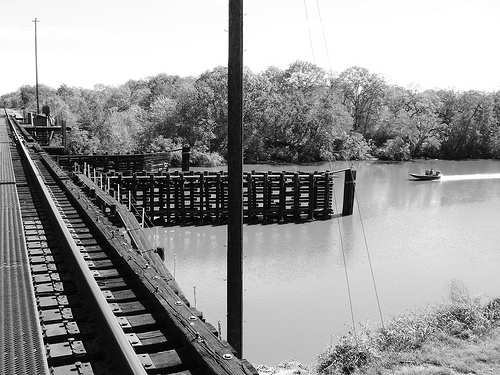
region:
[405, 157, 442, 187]
boat traveling in the waterway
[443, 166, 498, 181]
wake behind the boat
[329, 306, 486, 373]
bank of the river in the foreground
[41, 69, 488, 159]
trees on the bank of the river in the background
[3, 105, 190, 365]
train tracks on bridge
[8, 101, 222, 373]
bridge over top of the river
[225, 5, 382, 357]
utility poles with wires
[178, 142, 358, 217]
wood pillars in the water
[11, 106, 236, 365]
bolts in the bridge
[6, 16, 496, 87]
sky above the treeline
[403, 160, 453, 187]
The boat is in the water.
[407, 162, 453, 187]
The boat has a motor.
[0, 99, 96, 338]
No trains are on the train tracks.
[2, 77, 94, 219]
The trees are next to the train tracks.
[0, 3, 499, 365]
The picture is in black and white.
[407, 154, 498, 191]
The boat left tracks in the water.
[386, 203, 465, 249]
The water is flat.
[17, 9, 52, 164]
The pole is next to the train tracks.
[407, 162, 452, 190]
a boat in the water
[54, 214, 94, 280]
metal train rail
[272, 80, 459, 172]
trees beside the water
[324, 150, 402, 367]
cables fastened to the ground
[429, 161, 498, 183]
the wake of a boat in the water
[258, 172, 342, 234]
wooden piers in the water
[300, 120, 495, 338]
a river with a boat in it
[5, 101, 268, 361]
train tracks going across a river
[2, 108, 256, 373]
Wooden railway bridge crossing river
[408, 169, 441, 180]
Powerboat moving in river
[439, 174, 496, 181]
Wave wake caused by power boat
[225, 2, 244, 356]
Wooden utility power pole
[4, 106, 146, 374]
Metal railroad track on bridge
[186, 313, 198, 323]
Bolt and washer attaching bridge pieces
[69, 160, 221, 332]
Pedestrian walkway alongside of bridge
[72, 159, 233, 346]
Cable fence along bridge walkway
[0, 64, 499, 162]
Trees along river bank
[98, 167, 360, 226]
Channel fence for river navigation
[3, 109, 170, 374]
railroad tracks over water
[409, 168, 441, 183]
boat in a river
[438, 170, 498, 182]
wake created by a boat in a river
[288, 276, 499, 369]
grass on the near bank of the river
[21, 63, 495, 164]
trees on the far bank of a river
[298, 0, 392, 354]
wires connected to a pole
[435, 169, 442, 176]
motor on the back of a boat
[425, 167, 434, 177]
person in a boat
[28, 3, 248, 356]
two tall poles along railroad track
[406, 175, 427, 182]
shadow cast by a boat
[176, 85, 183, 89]
A green leaf on a plant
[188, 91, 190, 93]
A green leaf on a plant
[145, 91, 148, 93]
A green leaf on a plant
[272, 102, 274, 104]
A green leaf on a plant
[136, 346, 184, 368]
wooden board on bridge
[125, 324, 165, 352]
wooden board on bridge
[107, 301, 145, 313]
wooden board on bridge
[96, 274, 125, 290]
wooden board on bridge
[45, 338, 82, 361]
wooden board on bridge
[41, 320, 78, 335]
wooden board on bridge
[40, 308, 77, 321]
wooden board on bridge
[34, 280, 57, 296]
wooden board on bridge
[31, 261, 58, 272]
wooden board on bridge